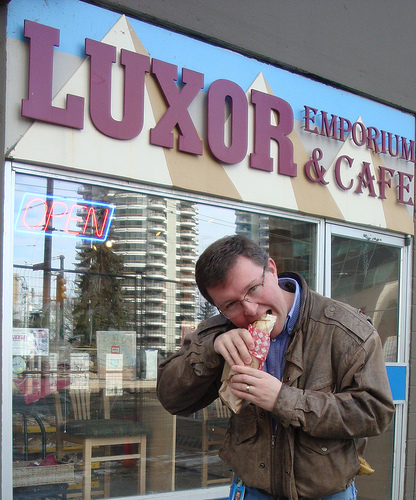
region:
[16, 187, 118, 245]
red and blue neon sign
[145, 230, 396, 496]
man eating a sandwich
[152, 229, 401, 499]
man wearing a brown coat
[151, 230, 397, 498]
man in front of a cafe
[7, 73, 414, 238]
sign for Luxor Emporium and Cafe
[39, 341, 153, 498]
wooden chair in the window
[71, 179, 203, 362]
reflection of a building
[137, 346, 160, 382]
metal napkin holder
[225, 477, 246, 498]
ID card clipped to coat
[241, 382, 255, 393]
wedding ring on his finger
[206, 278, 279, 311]
a man wearing glasses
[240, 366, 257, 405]
a man wearing a ring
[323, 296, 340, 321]
a button on a jacket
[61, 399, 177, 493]
a stool in the window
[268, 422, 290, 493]
a zipper on a jacket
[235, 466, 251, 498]
a tag on the man pants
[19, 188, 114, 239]
an open sign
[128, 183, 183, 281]
reflection of a building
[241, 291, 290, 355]
a man eating food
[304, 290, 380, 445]
a brown leather jacket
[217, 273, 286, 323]
He is wearing glasses.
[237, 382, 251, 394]
He has a silver ring.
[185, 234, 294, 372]
He is eating.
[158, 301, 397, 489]
His jacket is brown.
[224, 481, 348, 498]
His pants are jeans.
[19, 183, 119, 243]
The sign is lit up.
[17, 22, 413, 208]
The letters are maroon.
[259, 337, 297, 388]
His shirt is blue.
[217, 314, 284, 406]
The food is in paper.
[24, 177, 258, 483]
reflections in the mirror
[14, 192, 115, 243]
Blue and red neon open sign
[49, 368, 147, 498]
Wood chair with green cushion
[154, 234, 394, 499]
Man eating a sandwich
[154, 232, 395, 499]
Man wearing a brown leather jacket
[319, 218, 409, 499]
Glass door with a blue handle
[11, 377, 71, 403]
Cloth red tablecloth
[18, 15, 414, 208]
Burgundy letter signs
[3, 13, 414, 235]
Graphics of pyramids on a store sign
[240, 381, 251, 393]
Gold band on a mans finger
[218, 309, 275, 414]
Brown and checkered wrapping on a pita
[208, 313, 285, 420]
sandwich in man's hands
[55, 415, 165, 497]
chair behind the window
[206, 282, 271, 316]
glasses on a man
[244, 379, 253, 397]
ring on a man's hand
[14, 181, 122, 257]
open sign on a window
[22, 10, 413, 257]
sign of a business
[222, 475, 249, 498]
hand sanitizer on man's jeans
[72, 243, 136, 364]
reflection of a tree in window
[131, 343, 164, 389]
napkin dispenser on a table